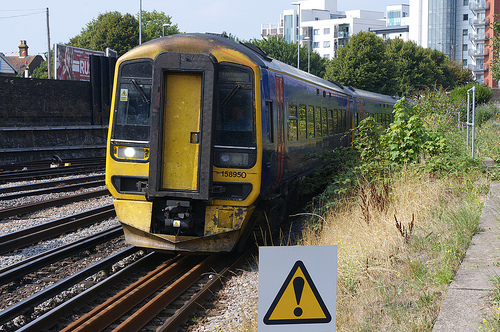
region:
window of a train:
[212, 75, 257, 142]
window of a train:
[280, 102, 300, 141]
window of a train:
[303, 105, 309, 142]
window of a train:
[310, 102, 322, 134]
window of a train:
[323, 105, 333, 131]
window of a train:
[335, 116, 349, 132]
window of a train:
[351, 112, 361, 124]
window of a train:
[375, 112, 385, 127]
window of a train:
[385, 108, 395, 127]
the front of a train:
[86, 32, 311, 247]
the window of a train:
[87, 41, 162, 152]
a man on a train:
[209, 81, 274, 138]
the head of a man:
[219, 100, 255, 127]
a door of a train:
[151, 60, 234, 195]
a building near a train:
[302, 0, 424, 102]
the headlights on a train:
[98, 126, 168, 196]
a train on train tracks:
[86, 41, 388, 268]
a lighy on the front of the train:
[119, 133, 140, 166]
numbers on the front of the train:
[220, 156, 260, 183]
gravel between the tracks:
[29, 192, 65, 229]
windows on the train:
[286, 100, 319, 137]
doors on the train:
[273, 70, 288, 174]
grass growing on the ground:
[412, 201, 452, 251]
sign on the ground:
[261, 269, 354, 318]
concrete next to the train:
[448, 246, 498, 311]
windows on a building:
[459, 15, 477, 50]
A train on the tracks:
[109, 30, 434, 262]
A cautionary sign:
[251, 240, 343, 329]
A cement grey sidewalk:
[424, 167, 496, 330]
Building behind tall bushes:
[248, 0, 496, 97]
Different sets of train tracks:
[1, 170, 223, 327]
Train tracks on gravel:
[16, 247, 214, 328]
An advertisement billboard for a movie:
[52, 41, 102, 84]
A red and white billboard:
[53, 41, 108, 84]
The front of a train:
[108, 42, 252, 256]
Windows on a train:
[286, 103, 348, 146]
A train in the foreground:
[98, 29, 418, 272]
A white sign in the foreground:
[243, 236, 350, 331]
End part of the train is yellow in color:
[85, 24, 270, 266]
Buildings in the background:
[248, 2, 498, 92]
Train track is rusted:
[56, 248, 253, 330]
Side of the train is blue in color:
[258, 47, 406, 235]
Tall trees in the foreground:
[25, 2, 477, 92]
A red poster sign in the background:
[42, 33, 108, 88]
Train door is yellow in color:
[143, 48, 213, 198]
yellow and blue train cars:
[105, 30, 402, 249]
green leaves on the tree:
[390, 66, 401, 78]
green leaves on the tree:
[338, 49, 359, 74]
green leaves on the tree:
[390, 149, 413, 170]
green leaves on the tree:
[350, 64, 380, 94]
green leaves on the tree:
[272, 39, 284, 49]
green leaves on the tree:
[138, 9, 171, 26]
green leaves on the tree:
[272, 26, 301, 58]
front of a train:
[112, 37, 261, 244]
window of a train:
[215, 69, 250, 148]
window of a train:
[112, 61, 152, 142]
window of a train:
[265, 101, 276, 142]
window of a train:
[308, 106, 316, 141]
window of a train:
[326, 109, 333, 129]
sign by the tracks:
[257, 244, 337, 329]